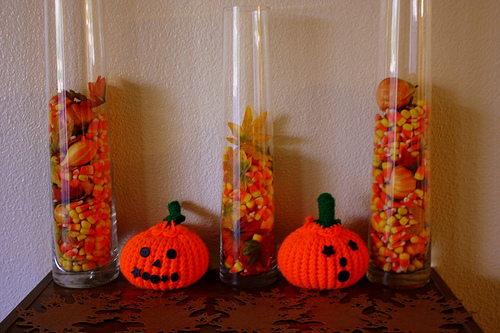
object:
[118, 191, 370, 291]
pumpkin counter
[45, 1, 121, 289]
container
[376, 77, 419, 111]
candy piece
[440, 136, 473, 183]
ground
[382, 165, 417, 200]
pumpkin candy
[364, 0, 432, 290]
bottle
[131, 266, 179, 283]
mouth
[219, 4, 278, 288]
bottle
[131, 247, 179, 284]
pumpkin face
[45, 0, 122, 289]
glass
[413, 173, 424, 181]
candy corn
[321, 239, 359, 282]
face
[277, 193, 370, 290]
orange pumpkin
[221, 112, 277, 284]
candy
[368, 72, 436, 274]
candy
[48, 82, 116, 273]
candy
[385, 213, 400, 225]
candy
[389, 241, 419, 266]
candy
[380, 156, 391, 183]
candy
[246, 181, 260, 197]
candy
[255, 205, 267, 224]
candy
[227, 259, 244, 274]
candy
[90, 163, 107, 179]
candy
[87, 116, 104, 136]
candy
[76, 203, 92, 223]
candy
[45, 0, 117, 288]
vase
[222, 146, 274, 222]
card corn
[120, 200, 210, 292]
pumpkin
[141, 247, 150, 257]
eye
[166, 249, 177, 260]
eye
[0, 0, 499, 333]
wall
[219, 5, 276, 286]
glass cylinder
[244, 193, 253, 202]
candy corn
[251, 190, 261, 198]
candy corn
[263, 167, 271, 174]
candy corn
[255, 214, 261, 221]
candy corn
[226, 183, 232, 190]
candy corn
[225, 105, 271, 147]
flower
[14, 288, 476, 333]
surface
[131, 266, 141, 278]
star